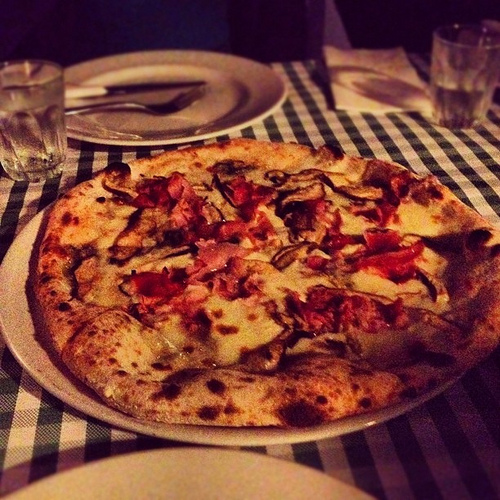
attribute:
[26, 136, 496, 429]
pizza — delicious looking, slightly burnt, fluffy, round, pink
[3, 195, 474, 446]
plate — white, empty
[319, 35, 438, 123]
napkin — folded, white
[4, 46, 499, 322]
table cloth — checkered, patterned, green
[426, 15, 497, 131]
glass — half full, full, sweaty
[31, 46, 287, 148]
plate — white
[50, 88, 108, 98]
knife handle — white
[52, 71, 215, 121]
silverware — shiny